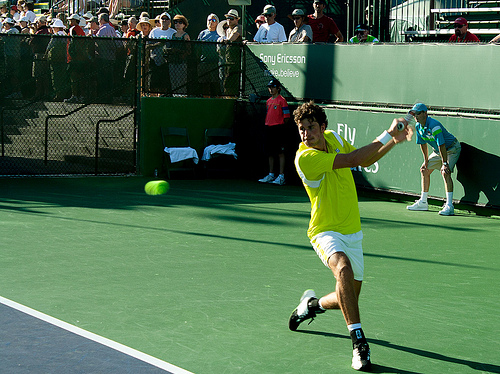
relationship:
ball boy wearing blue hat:
[406, 101, 463, 217] [408, 102, 428, 114]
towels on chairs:
[161, 139, 243, 169] [147, 112, 246, 196]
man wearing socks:
[286, 99, 414, 372] [299, 295, 324, 317]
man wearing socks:
[286, 99, 414, 372] [344, 325, 366, 342]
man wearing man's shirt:
[289, 100, 416, 372] [290, 125, 364, 239]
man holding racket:
[289, 100, 416, 372] [396, 109, 415, 131]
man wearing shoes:
[286, 99, 414, 372] [271, 293, 422, 370]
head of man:
[293, 100, 328, 145] [289, 100, 416, 372]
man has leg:
[286, 99, 414, 372] [324, 244, 364, 338]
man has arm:
[289, 100, 416, 372] [301, 127, 393, 170]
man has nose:
[286, 99, 414, 372] [301, 127, 314, 144]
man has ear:
[286, 99, 414, 372] [317, 112, 331, 132]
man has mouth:
[289, 100, 416, 372] [297, 132, 317, 143]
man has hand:
[289, 100, 416, 372] [386, 112, 418, 144]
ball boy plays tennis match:
[406, 101, 463, 217] [126, 84, 455, 354]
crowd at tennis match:
[4, 6, 314, 40] [126, 94, 438, 372]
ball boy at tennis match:
[252, 79, 289, 189] [93, 50, 463, 371]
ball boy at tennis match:
[409, 101, 464, 216] [93, 50, 463, 371]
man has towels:
[286, 99, 414, 372] [164, 142, 236, 164]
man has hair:
[286, 99, 414, 372] [291, 101, 327, 125]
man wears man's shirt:
[289, 100, 416, 372] [290, 125, 364, 239]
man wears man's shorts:
[286, 99, 414, 372] [309, 229, 364, 283]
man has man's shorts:
[289, 100, 416, 372] [309, 223, 365, 283]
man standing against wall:
[286, 99, 414, 372] [130, 95, 498, 215]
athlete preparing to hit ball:
[269, 96, 424, 371] [139, 173, 172, 198]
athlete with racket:
[269, 96, 424, 371] [379, 97, 425, 134]